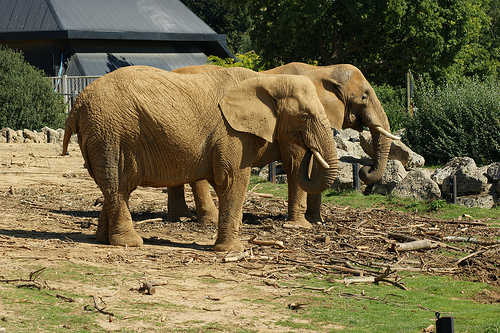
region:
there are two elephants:
[32, 37, 408, 270]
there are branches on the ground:
[260, 215, 414, 305]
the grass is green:
[345, 285, 410, 330]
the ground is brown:
[17, 147, 59, 197]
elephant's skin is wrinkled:
[80, 78, 206, 184]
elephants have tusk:
[311, 125, 437, 197]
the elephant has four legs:
[92, 172, 322, 302]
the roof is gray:
[70, 51, 213, 103]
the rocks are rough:
[346, 135, 487, 221]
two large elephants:
[61, 45, 413, 262]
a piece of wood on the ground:
[386, 232, 438, 257]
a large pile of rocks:
[401, 158, 499, 214]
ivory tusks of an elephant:
[370, 120, 403, 145]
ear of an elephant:
[216, 70, 287, 147]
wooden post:
[400, 67, 419, 126]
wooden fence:
[37, 74, 117, 130]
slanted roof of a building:
[0, 3, 215, 53]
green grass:
[366, 308, 420, 332]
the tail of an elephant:
[53, 110, 85, 159]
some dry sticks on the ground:
[326, 215, 443, 275]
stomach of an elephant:
[135, 111, 199, 168]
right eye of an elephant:
[297, 105, 312, 124]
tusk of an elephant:
[371, 120, 398, 151]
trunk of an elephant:
[295, 159, 327, 192]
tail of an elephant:
[58, 117, 75, 162]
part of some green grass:
[359, 285, 411, 328]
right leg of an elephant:
[218, 183, 242, 233]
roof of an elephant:
[69, 10, 184, 31]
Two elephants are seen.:
[106, 46, 374, 228]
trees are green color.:
[337, 20, 472, 48]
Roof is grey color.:
[35, 5, 200, 43]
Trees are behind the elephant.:
[240, 8, 442, 58]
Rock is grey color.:
[395, 140, 485, 190]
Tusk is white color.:
[372, 122, 399, 143]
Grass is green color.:
[335, 286, 405, 326]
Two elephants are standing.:
[82, 171, 342, 262]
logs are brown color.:
[322, 213, 427, 270]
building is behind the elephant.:
[27, 15, 202, 76]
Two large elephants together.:
[48, 32, 448, 307]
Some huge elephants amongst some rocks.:
[104, 9, 441, 274]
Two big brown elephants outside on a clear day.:
[54, 16, 462, 266]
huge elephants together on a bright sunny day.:
[30, 34, 445, 256]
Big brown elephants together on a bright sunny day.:
[55, 26, 458, 284]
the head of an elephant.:
[250, 76, 342, 192]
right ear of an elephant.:
[220, 54, 276, 151]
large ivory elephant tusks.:
[300, 151, 335, 190]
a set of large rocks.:
[399, 149, 486, 197]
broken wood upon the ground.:
[311, 213, 470, 278]